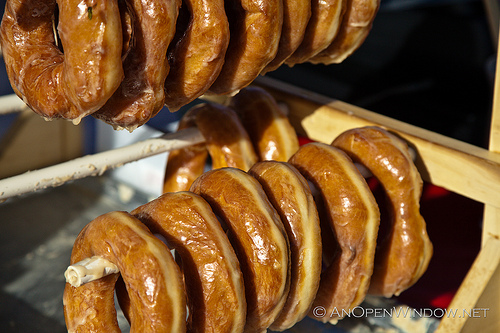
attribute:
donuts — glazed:
[56, 210, 178, 330]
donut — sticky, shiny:
[57, 206, 189, 331]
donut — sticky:
[111, 185, 253, 331]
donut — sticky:
[173, 162, 297, 330]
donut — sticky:
[240, 152, 329, 332]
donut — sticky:
[280, 136, 385, 326]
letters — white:
[312, 303, 489, 320]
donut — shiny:
[4, 0, 126, 127]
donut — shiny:
[91, 0, 180, 135]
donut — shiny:
[127, 191, 248, 331]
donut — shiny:
[330, 125, 433, 295]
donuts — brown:
[1, 2, 426, 232]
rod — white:
[2, 102, 290, 207]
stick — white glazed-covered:
[0, 125, 205, 201]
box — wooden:
[255, 77, 498, 284]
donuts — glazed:
[180, 170, 363, 317]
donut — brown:
[130, 184, 340, 304]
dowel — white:
[2, 125, 203, 187]